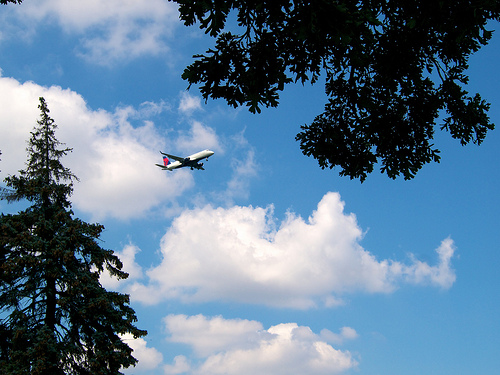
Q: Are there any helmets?
A: No, there are no helmets.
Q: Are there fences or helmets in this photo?
A: No, there are no helmets or fences.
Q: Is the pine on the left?
A: Yes, the pine is on the left of the image.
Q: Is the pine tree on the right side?
A: No, the pine tree is on the left of the image.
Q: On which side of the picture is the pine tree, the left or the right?
A: The pine tree is on the left of the image.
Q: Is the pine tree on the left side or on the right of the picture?
A: The pine tree is on the left of the image.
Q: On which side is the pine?
A: The pine is on the left of the image.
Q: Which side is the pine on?
A: The pine is on the left of the image.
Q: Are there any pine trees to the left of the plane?
A: Yes, there is a pine tree to the left of the plane.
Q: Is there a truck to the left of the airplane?
A: No, there is a pine tree to the left of the airplane.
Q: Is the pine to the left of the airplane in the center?
A: Yes, the pine is to the left of the airplane.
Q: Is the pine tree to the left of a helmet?
A: No, the pine tree is to the left of the airplane.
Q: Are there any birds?
A: No, there are no birds.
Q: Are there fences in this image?
A: No, there are no fences.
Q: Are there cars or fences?
A: No, there are no fences or cars.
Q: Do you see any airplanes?
A: Yes, there is an airplane.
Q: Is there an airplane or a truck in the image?
A: Yes, there is an airplane.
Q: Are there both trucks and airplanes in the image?
A: No, there is an airplane but no trucks.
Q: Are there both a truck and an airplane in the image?
A: No, there is an airplane but no trucks.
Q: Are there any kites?
A: No, there are no kites.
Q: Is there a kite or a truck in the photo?
A: No, there are no kites or trucks.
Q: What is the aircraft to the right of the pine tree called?
A: The aircraft is an airplane.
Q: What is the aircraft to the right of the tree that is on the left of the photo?
A: The aircraft is an airplane.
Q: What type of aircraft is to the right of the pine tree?
A: The aircraft is an airplane.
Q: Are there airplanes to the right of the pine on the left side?
A: Yes, there is an airplane to the right of the pine.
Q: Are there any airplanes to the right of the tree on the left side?
A: Yes, there is an airplane to the right of the pine.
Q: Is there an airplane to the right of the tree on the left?
A: Yes, there is an airplane to the right of the pine.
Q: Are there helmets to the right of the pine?
A: No, there is an airplane to the right of the pine.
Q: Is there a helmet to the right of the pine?
A: No, there is an airplane to the right of the pine.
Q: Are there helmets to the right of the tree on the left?
A: No, there is an airplane to the right of the pine.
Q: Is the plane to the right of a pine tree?
A: Yes, the plane is to the right of a pine tree.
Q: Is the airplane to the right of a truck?
A: No, the airplane is to the right of a pine tree.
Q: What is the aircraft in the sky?
A: The aircraft is an airplane.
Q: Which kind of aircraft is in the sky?
A: The aircraft is an airplane.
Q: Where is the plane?
A: The plane is in the sky.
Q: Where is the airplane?
A: The plane is in the sky.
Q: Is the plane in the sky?
A: Yes, the plane is in the sky.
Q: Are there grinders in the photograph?
A: No, there are no grinders.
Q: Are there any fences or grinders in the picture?
A: No, there are no grinders or fences.